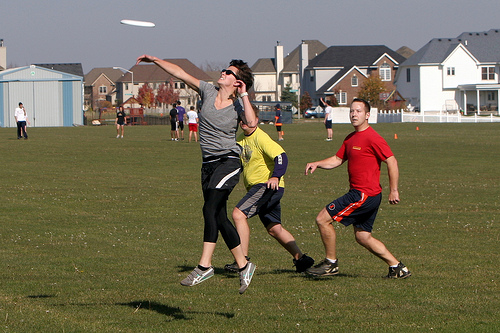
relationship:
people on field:
[223, 102, 316, 273] [6, 125, 499, 310]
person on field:
[168, 102, 180, 138] [3, 122, 497, 332]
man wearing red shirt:
[303, 97, 412, 279] [333, 128, 393, 196]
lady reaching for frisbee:
[124, 50, 257, 285] [117, 11, 159, 30]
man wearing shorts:
[303, 97, 412, 279] [324, 186, 383, 233]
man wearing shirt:
[303, 97, 412, 279] [337, 129, 391, 201]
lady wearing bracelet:
[135, 53, 258, 296] [235, 85, 250, 102]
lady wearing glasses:
[135, 53, 258, 296] [198, 47, 265, 87]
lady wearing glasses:
[135, 53, 258, 296] [213, 59, 243, 84]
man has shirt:
[303, 97, 412, 279] [337, 124, 405, 204]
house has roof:
[375, 43, 466, 117] [404, 30, 482, 61]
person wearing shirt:
[13, 102, 29, 140] [14, 107, 25, 121]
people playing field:
[65, 21, 430, 300] [6, 125, 499, 310]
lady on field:
[135, 53, 258, 296] [6, 125, 499, 310]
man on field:
[303, 97, 412, 279] [14, 112, 474, 331]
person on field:
[114, 105, 126, 138] [14, 112, 474, 331]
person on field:
[10, 101, 30, 140] [14, 112, 474, 331]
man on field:
[303, 97, 412, 279] [3, 122, 497, 332]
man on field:
[303, 97, 412, 279] [66, 148, 169, 263]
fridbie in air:
[118, 18, 155, 28] [13, 10, 466, 54]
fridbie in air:
[119, 18, 156, 28] [42, 1, 142, 104]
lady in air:
[135, 53, 258, 296] [102, 30, 168, 174]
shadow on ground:
[23, 291, 240, 325] [80, 273, 243, 331]